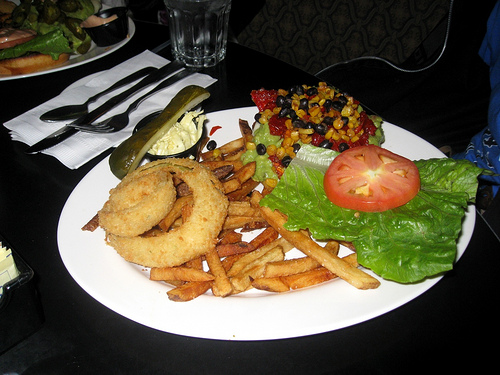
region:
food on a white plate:
[57, 100, 472, 337]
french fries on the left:
[82, 131, 379, 301]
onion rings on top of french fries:
[100, 158, 227, 273]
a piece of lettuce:
[271, 132, 476, 285]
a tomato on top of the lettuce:
[325, 140, 425, 215]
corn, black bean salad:
[248, 75, 375, 158]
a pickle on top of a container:
[105, 65, 207, 185]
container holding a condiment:
[140, 110, 205, 153]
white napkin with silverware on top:
[5, 37, 241, 177]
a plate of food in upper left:
[0, 1, 161, 85]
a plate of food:
[76, 76, 479, 348]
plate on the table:
[82, 90, 485, 333]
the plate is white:
[56, 84, 449, 343]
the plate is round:
[62, 77, 475, 346]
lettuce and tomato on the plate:
[273, 133, 455, 252]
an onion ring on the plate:
[94, 147, 235, 267]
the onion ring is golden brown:
[95, 152, 227, 262]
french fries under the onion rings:
[130, 145, 331, 290]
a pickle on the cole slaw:
[103, 82, 210, 158]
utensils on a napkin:
[27, 61, 169, 148]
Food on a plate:
[56, 98, 478, 346]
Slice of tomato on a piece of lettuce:
[263, 140, 480, 285]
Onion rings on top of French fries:
[99, 131, 378, 303]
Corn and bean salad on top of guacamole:
[243, 84, 385, 176]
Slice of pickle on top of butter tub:
[108, 80, 213, 178]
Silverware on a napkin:
[3, 53, 218, 170]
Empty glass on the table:
[167, 0, 226, 69]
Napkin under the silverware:
[5, 47, 216, 170]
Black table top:
[0, 14, 499, 369]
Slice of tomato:
[323, 145, 420, 210]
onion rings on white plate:
[61, 154, 235, 256]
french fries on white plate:
[197, 196, 322, 306]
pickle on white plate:
[119, 84, 196, 164]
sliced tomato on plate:
[330, 141, 422, 216]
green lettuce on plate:
[271, 161, 451, 302]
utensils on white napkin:
[34, 52, 184, 167]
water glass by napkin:
[167, 18, 221, 70]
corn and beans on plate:
[253, 77, 361, 142]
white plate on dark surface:
[47, 71, 451, 362]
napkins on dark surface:
[44, 53, 159, 170]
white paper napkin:
[4, 50, 215, 170]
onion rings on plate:
[99, 158, 224, 269]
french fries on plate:
[90, 124, 378, 301]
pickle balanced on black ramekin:
[109, 84, 209, 177]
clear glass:
[165, 0, 228, 67]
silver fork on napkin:
[67, 64, 208, 133]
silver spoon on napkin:
[35, 65, 158, 122]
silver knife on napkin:
[24, 61, 184, 153]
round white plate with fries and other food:
[55, 103, 479, 338]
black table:
[2, 19, 497, 373]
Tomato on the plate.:
[324, 142, 421, 210]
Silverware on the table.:
[27, 60, 198, 154]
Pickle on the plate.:
[109, 83, 211, 178]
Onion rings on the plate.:
[97, 155, 229, 269]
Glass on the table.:
[161, 0, 230, 70]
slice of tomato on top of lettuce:
[257, 140, 483, 284]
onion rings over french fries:
[97, 117, 380, 304]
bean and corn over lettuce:
[237, 77, 385, 182]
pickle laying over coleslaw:
[107, 83, 207, 178]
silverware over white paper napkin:
[3, 47, 216, 169]